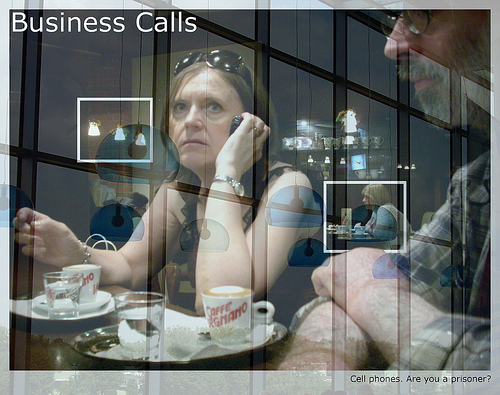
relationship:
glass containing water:
[111, 289, 166, 359] [114, 307, 162, 362]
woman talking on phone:
[10, 48, 330, 339] [226, 111, 244, 135]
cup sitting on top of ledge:
[294, 135, 311, 148] [274, 148, 394, 159]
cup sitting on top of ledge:
[280, 135, 294, 148] [274, 148, 394, 159]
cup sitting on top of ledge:
[321, 135, 333, 149] [274, 148, 394, 159]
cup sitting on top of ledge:
[332, 136, 342, 146] [274, 148, 394, 159]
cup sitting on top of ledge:
[370, 135, 385, 147] [274, 148, 394, 159]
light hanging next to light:
[86, 120, 102, 138] [110, 123, 125, 139]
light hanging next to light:
[110, 123, 125, 139] [133, 130, 146, 146]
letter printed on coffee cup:
[240, 300, 248, 312] [198, 283, 274, 345]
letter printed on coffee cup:
[232, 304, 242, 318] [198, 283, 274, 345]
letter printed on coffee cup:
[228, 309, 235, 321] [198, 283, 274, 345]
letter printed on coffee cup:
[218, 313, 228, 325] [198, 283, 274, 345]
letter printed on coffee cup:
[222, 300, 232, 311] [198, 283, 274, 345]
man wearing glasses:
[272, 10, 484, 367] [379, 9, 431, 38]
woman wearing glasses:
[10, 48, 330, 339] [171, 48, 254, 90]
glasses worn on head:
[171, 48, 254, 90] [160, 59, 278, 174]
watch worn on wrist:
[210, 173, 245, 198] [208, 163, 242, 187]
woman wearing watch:
[10, 48, 330, 339] [210, 173, 245, 198]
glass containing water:
[41, 269, 81, 319] [43, 281, 80, 312]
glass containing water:
[111, 289, 166, 359] [116, 308, 164, 358]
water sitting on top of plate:
[114, 305, 163, 359] [66, 315, 288, 366]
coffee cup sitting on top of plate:
[200, 290, 273, 346] [66, 315, 288, 366]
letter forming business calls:
[10, 10, 28, 32] [11, 10, 197, 35]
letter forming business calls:
[45, 15, 58, 32] [11, 10, 197, 35]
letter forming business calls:
[84, 15, 98, 33] [11, 10, 197, 35]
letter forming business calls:
[134, 10, 154, 33] [11, 10, 197, 35]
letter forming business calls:
[184, 15, 197, 32] [11, 10, 197, 35]